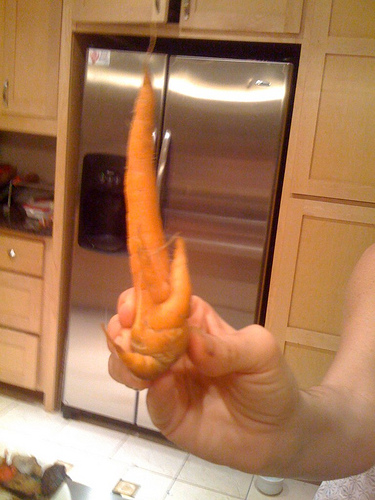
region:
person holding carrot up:
[91, 8, 231, 403]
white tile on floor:
[7, 370, 340, 497]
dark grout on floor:
[7, 394, 286, 495]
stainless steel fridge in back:
[12, 28, 317, 494]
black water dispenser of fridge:
[71, 118, 164, 276]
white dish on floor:
[232, 444, 307, 496]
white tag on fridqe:
[83, 36, 111, 74]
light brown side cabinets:
[200, 0, 366, 424]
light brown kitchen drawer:
[0, 210, 69, 396]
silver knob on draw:
[3, 234, 31, 280]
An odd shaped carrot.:
[113, 56, 207, 395]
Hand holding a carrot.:
[90, 264, 308, 471]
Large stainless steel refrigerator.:
[82, 36, 293, 483]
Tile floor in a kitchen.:
[16, 400, 138, 463]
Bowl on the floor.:
[251, 468, 285, 499]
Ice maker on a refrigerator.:
[78, 143, 132, 264]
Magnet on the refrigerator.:
[86, 46, 115, 67]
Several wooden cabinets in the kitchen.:
[281, 21, 365, 334]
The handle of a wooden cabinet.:
[2, 80, 11, 104]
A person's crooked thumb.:
[185, 327, 294, 384]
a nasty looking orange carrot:
[121, 84, 192, 374]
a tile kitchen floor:
[105, 453, 183, 499]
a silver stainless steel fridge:
[65, 49, 294, 449]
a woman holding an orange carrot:
[112, 74, 293, 452]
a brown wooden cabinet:
[0, 225, 46, 375]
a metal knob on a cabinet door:
[7, 249, 13, 259]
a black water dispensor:
[81, 150, 130, 250]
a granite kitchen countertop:
[0, 159, 54, 226]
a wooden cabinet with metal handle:
[1, 0, 63, 115]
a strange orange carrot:
[98, 78, 201, 371]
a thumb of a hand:
[184, 314, 285, 394]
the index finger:
[105, 284, 150, 327]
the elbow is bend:
[314, 356, 374, 486]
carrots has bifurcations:
[102, 221, 204, 388]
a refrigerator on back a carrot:
[56, 55, 294, 458]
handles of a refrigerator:
[134, 121, 175, 234]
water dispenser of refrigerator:
[72, 145, 134, 260]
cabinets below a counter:
[2, 231, 43, 398]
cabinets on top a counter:
[2, 82, 62, 125]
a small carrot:
[164, 231, 197, 324]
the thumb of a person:
[169, 309, 292, 381]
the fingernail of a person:
[171, 322, 235, 385]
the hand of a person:
[106, 276, 260, 411]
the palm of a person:
[150, 358, 265, 467]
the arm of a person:
[105, 215, 371, 395]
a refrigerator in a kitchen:
[68, 208, 276, 368]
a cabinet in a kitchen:
[13, 216, 107, 362]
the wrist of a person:
[251, 377, 329, 476]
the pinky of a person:
[149, 337, 193, 446]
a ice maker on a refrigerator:
[71, 125, 170, 271]